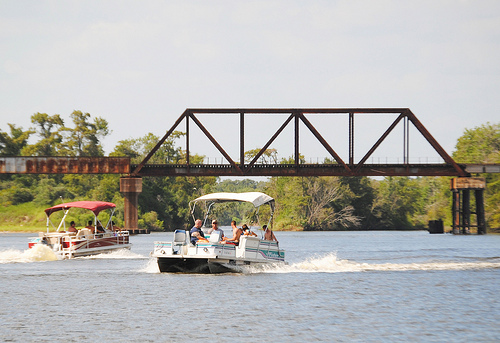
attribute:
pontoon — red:
[28, 201, 134, 258]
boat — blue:
[152, 192, 287, 275]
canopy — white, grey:
[189, 192, 276, 242]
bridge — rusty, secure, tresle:
[1, 107, 500, 234]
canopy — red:
[44, 200, 118, 235]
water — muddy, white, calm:
[0, 225, 500, 342]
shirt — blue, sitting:
[188, 218, 208, 245]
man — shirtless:
[223, 221, 241, 244]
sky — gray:
[2, 1, 497, 180]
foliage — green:
[1, 109, 499, 232]